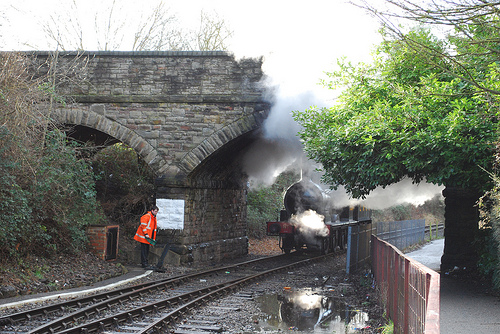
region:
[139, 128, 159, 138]
grey brick on bridge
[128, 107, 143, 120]
grey brick on bridge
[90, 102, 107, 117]
grey brick on bridge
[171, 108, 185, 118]
grey brick on bridge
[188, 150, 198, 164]
grey brick on bridge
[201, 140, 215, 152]
grey brick on bridge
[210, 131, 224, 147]
grey brick on bridge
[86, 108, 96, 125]
grey brick on bridge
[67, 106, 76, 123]
grey brick on bridge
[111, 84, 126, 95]
grey brick on bridge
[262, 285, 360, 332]
reflection in the water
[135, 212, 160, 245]
an orange rain jacket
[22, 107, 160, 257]
arch way under the bridge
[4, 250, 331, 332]
metal train tracks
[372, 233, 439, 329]
a short fence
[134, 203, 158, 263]
a man standing under the bridge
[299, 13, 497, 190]
green leaves on the tree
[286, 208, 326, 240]
steam from the train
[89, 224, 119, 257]
a brick box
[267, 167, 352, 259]
train on the tracks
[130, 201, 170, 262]
man wearing orange safety jacket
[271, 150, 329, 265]
front of steam locomotive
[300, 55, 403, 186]
green leafy tree branches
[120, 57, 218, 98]
gray stone wall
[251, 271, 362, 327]
water reflecting white light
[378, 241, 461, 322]
red wooden fence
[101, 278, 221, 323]
gray black railroad tracks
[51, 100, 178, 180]
gray stoned archway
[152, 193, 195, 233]
white square spot on wall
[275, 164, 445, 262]
Train coming around a bend.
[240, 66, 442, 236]
Steam from the train.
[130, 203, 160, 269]
A man standing near the tracks.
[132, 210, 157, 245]
A bright orange coat with white stripes.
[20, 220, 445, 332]
A winding train track.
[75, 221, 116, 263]
Small brick structure with a black door.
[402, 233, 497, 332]
A cement walkway.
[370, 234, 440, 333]
Red fence near the walkway.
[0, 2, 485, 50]
light in daytime sky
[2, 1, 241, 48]
trees with no leaves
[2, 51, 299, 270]
arches under stone bridge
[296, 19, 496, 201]
green leaves on trees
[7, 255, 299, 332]
metal rails of train track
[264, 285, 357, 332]
reflection on water surface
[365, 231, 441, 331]
fence overlooking train tracks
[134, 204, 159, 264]
man in orange coat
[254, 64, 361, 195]
steam from locomotive engine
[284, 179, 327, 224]
front of locomotive train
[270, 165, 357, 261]
train under the stone bridge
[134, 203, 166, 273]
workman by the stone bridge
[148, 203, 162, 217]
Head of a man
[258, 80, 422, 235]
Smoke coming from the train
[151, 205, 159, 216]
Head of a man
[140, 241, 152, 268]
Pants on a man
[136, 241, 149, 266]
Black pants on a man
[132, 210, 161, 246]
Coat on a man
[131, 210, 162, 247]
Orange coat on a man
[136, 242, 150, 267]
Pants on a man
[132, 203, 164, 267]
human stands next to tracks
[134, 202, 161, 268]
human stands next to bridge